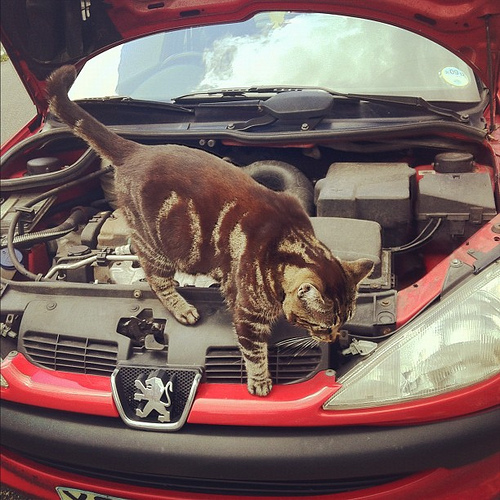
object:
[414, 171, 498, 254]
fuse box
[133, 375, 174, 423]
car symbol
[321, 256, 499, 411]
head lamp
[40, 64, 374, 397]
cat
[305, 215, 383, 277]
part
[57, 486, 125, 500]
license plate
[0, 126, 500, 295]
engine compartment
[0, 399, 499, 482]
bumper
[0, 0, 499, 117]
hood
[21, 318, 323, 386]
grill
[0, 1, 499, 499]
car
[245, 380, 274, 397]
cat paw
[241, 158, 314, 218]
engine part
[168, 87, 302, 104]
windshield wiper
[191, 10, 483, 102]
reflection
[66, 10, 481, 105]
clouded sky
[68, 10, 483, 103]
windshield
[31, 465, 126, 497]
plate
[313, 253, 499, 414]
headlight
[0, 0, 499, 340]
open hood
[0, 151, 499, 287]
engine